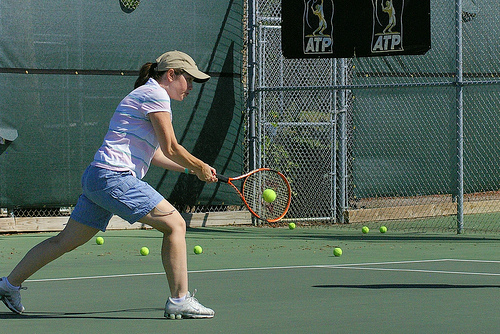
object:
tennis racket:
[213, 166, 293, 223]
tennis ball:
[262, 188, 277, 203]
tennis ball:
[333, 247, 344, 257]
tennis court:
[0, 209, 500, 333]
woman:
[0, 46, 224, 323]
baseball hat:
[153, 49, 212, 85]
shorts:
[69, 164, 166, 233]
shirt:
[87, 76, 173, 180]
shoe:
[162, 287, 216, 320]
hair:
[134, 61, 186, 89]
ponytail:
[133, 62, 158, 90]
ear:
[167, 68, 176, 82]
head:
[154, 49, 196, 102]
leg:
[103, 174, 217, 321]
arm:
[148, 100, 204, 170]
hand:
[193, 163, 217, 181]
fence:
[246, 0, 500, 240]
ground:
[0, 188, 500, 334]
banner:
[278, 0, 432, 60]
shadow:
[139, 0, 255, 234]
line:
[23, 258, 450, 281]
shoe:
[0, 275, 29, 316]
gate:
[255, 18, 349, 225]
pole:
[454, 0, 465, 235]